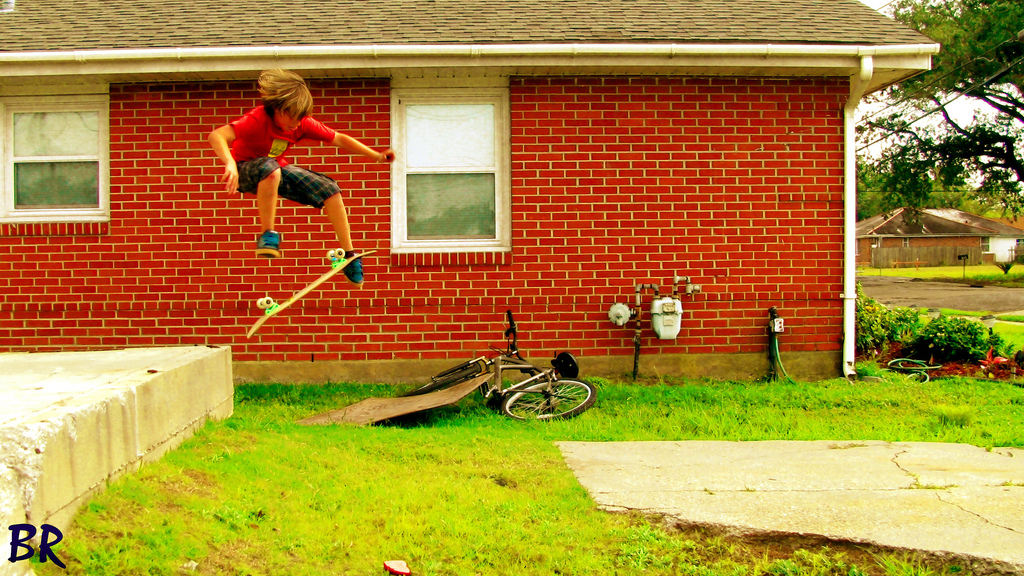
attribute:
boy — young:
[192, 47, 382, 269]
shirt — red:
[182, 112, 345, 179]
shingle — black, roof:
[12, 2, 935, 35]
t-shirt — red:
[229, 103, 341, 165]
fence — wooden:
[871, 242, 989, 268]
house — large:
[857, 201, 990, 268]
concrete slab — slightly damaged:
[1, 343, 236, 574]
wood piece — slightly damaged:
[317, 369, 492, 426]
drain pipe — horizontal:
[5, 32, 942, 68]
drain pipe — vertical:
[846, 57, 879, 368]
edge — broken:
[549, 517, 1022, 559]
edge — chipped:
[1, 439, 31, 491]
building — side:
[6, 11, 922, 388]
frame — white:
[378, 48, 538, 288]